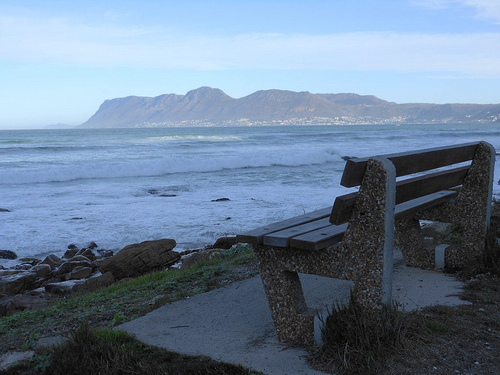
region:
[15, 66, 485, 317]
a bench by the water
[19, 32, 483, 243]
this pictue was probably taken during dusk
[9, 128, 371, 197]
the water looks agitated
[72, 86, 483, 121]
rocky terrain on the other side of the water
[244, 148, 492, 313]
a bench for sitting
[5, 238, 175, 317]
rocks near the bench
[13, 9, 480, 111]
the sky looks cloudy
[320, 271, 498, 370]
dead grass behind the bench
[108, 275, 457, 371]
concrete beneath the bench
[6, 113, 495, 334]
this picture could have been taken at sunrise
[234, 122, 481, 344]
a bench facing the sea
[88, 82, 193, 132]
mountain in the distance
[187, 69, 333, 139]
mountain in the distance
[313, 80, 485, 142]
mountain in the distance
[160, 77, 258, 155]
mountain in the distance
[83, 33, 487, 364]
view from a bench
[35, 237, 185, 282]
rocks at the shore line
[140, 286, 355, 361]
concrete platform for the bench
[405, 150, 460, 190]
two wooden boards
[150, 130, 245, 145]
white caps on the water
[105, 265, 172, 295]
small patch of grass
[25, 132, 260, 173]
an expanse of water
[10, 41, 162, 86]
clear, blue sky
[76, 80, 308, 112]
range of mountains at the horizon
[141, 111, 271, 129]
town at the foot of the mountain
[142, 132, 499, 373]
A bench on cement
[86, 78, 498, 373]
The bench overlooks the water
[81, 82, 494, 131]
The mountains sit along the water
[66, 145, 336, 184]
The waves crash along the rocks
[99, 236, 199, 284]
A rock next to the grass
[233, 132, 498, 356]
The bench is made of rocks and wood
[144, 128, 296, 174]
Two layers of waves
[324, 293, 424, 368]
A clump of grass next to the bench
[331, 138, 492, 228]
The back of the bench has two wooden slats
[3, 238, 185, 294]
A clump of rocks against the ground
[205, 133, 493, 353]
bench sitting on a slab of concrete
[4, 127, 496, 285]
large body of water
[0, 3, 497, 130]
light blue sky with white clouds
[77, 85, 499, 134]
cliffs along the water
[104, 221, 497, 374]
slab of concrete in the grass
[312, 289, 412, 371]
plants growing around the leg of the bench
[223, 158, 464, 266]
row of three wooden slabs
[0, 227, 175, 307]
rocks along the shore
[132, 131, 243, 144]
small wave in the water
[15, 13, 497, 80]
thin, long cloud